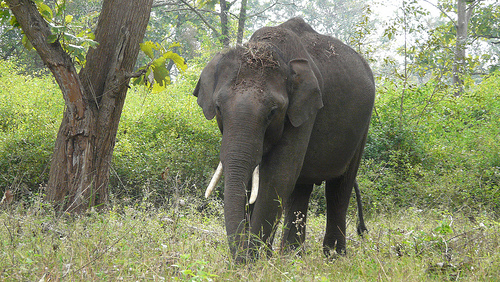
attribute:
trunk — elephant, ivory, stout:
[214, 104, 260, 269]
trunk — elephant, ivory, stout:
[216, 95, 273, 265]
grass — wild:
[0, 61, 496, 278]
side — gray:
[319, 68, 370, 168]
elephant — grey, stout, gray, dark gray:
[192, 14, 375, 265]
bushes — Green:
[4, 58, 497, 209]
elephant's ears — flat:
[191, 44, 326, 124]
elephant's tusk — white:
[202, 158, 262, 204]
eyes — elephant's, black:
[208, 97, 288, 124]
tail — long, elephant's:
[354, 170, 382, 232]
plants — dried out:
[4, 199, 223, 279]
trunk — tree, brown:
[8, 4, 157, 216]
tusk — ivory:
[246, 168, 264, 203]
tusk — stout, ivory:
[193, 159, 229, 212]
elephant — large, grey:
[199, 18, 386, 256]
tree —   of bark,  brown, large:
[10, 2, 155, 214]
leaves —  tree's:
[148, 55, 178, 87]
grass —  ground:
[0, 206, 500, 280]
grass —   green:
[0, 217, 500, 280]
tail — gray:
[352, 175, 372, 244]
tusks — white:
[193, 161, 267, 210]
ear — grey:
[276, 68, 417, 201]